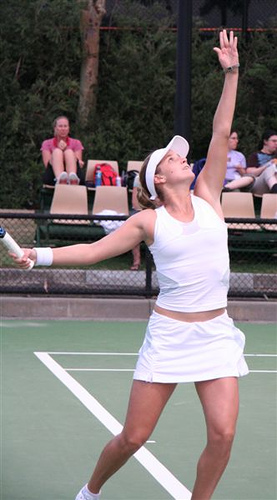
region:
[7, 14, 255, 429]
lady serving a tennis ball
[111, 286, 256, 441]
a short white tennis skirt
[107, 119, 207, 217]
a white sun visor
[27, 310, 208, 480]
a green tennis court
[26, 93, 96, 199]
audience member watching game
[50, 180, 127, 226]
two empty seats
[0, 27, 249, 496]
a female tennis player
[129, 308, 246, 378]
a white tennis skirt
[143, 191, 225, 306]
a white tennis top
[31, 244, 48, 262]
a white wrist band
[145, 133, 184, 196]
a white visor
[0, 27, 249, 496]
a tennis player serving ball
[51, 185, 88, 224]
a brown seat in stands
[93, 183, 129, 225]
a brown seat in stands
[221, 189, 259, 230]
a brown seat in stands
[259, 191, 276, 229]
a brown seat in stands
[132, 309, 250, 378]
woman wearing a short white skirt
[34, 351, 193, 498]
white line painted on top of the court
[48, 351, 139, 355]
line perpendicular to line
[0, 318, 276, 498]
court surface is green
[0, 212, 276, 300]
black metal fence behind woman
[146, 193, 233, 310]
white tank top above skirt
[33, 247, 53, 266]
white wrist band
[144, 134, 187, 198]
woman wearing a white visor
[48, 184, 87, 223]
an empty seat behind the fence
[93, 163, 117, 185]
a red backpack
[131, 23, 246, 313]
Female tennis player left hand reaching.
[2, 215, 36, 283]
Right hand grips tennis racket.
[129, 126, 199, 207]
White visor prevents sun stroke.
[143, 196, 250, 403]
White tank top and skirt.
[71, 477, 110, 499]
White socks right leg.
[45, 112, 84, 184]
Woman in pink knees bent.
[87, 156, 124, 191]
Chair holds backpack water bottle.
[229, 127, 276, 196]
Two spectators both eyeglasses.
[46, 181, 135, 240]
Tan chair seating for spectators.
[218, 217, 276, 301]
Heavy chain link fence.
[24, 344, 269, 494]
White lines on the court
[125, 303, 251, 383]
A white tennis skirt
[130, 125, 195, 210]
White visor on woman's head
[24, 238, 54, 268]
A white arm band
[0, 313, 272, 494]
The tennis court is green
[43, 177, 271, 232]
A row of empty beige seats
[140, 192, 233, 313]
A white tank top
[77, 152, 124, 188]
Red bag on a chair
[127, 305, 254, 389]
A white tennis skirt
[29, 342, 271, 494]
White lines on tennis court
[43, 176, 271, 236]
A row of brown chairs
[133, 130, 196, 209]
Woman wearing a white visor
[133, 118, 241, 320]
woman wearing a white visor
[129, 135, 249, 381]
woman wearing a white skirt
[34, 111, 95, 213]
woman watching a tennis match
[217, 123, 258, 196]
woman watching a tennis match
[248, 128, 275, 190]
woman watching a tennis match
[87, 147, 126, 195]
red backpack sitting on a chair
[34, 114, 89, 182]
woman wearing pink shirt